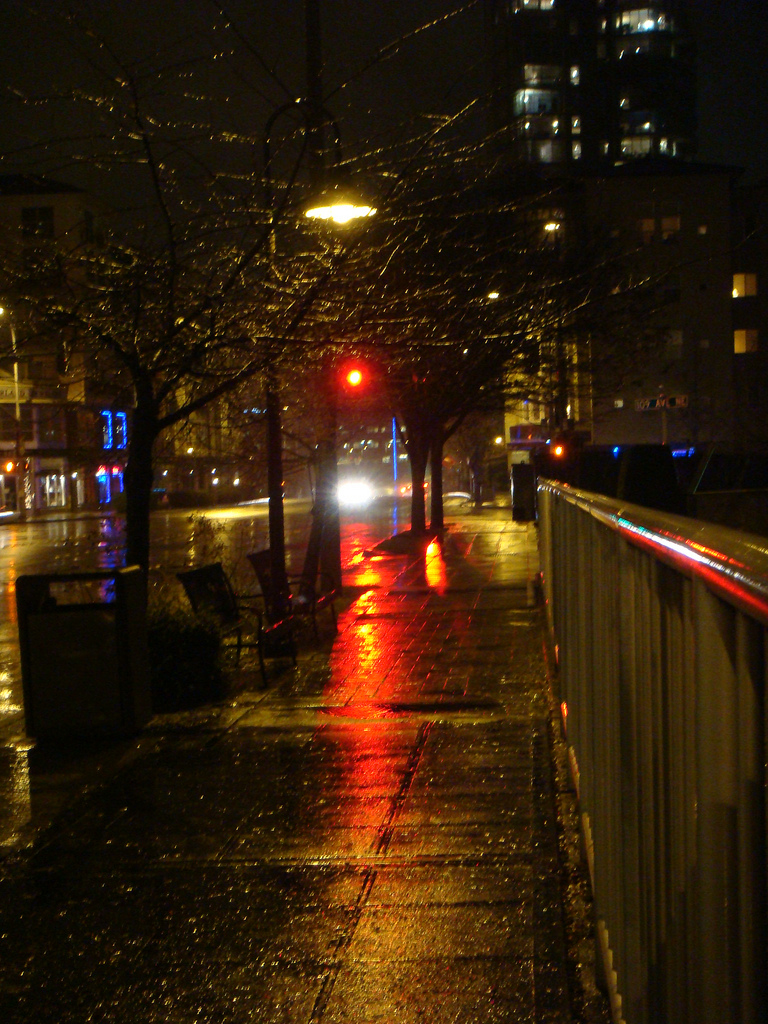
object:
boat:
[571, 142, 584, 164]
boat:
[544, 222, 561, 227]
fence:
[528, 476, 765, 1021]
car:
[385, 480, 419, 494]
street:
[0, 476, 566, 767]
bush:
[123, 607, 225, 709]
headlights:
[336, 479, 375, 511]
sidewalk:
[0, 487, 617, 1019]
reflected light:
[344, 521, 447, 685]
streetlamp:
[0, 304, 27, 523]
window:
[728, 325, 760, 360]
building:
[496, 6, 765, 461]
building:
[341, 0, 765, 492]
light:
[347, 370, 362, 386]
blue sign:
[97, 471, 112, 506]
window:
[100, 410, 130, 454]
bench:
[177, 562, 270, 688]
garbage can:
[14, 570, 152, 764]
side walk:
[0, 681, 636, 1018]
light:
[304, 202, 377, 226]